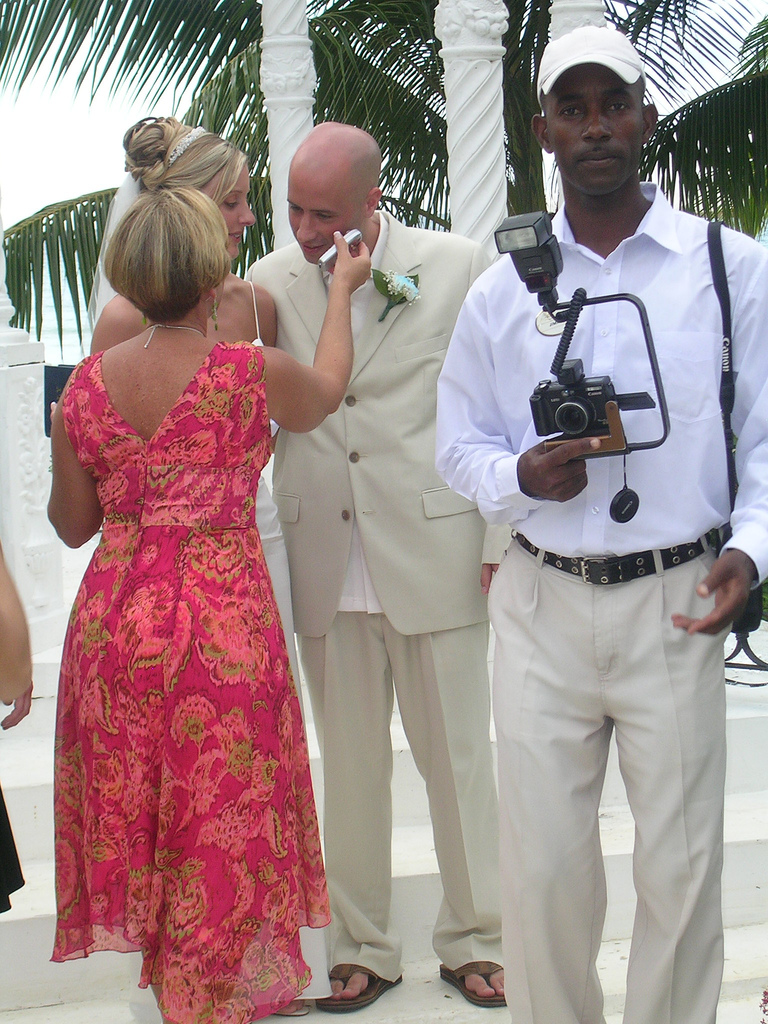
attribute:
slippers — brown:
[305, 950, 515, 1009]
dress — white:
[90, 283, 291, 1009]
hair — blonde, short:
[98, 182, 236, 322]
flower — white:
[369, 265, 421, 319]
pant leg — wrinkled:
[618, 580, 727, 1022]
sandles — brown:
[307, 952, 506, 1007]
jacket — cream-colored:
[242, 208, 509, 635]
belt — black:
[506, 517, 736, 587]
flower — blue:
[366, 263, 421, 322]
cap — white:
[521, 28, 663, 117]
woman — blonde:
[73, 167, 380, 667]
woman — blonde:
[40, 182, 387, 1015]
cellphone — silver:
[314, 226, 366, 267]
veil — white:
[84, 168, 146, 329]